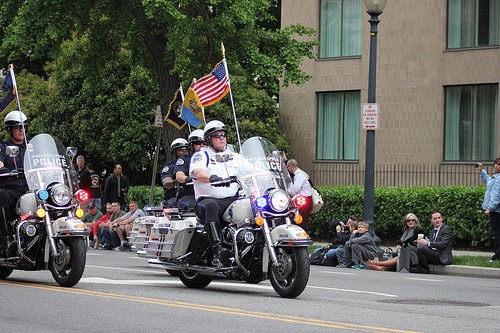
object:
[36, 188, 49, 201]
lights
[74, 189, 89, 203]
lights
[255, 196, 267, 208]
lights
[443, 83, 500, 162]
blind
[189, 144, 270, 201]
white shirt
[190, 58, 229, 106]
usa flag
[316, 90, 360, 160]
blind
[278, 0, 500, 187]
building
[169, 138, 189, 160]
helmet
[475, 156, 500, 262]
person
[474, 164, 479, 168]
camera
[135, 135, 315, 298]
motorcycle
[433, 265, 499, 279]
curb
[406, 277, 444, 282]
line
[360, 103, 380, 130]
sign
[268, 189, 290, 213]
light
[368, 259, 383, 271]
shoes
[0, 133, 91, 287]
bike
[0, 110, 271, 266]
police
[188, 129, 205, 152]
helmet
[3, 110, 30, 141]
helmet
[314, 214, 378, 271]
kids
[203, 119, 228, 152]
helmet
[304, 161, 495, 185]
fence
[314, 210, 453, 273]
people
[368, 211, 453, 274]
couple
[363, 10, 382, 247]
pole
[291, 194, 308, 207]
light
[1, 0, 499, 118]
background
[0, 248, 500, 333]
road